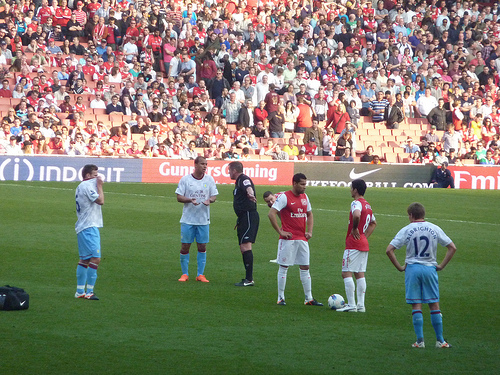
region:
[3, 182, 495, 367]
field where players are located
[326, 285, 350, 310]
ball on the field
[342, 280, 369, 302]
socks on the player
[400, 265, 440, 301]
shorts on the player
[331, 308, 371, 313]
shoes on the player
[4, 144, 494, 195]
banner on the wall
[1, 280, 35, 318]
bag on the ground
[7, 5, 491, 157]
crowd watching the game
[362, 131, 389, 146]
empty seats without people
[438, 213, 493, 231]
white line on field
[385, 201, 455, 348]
a soccer player wearing a white shirt and blue shorts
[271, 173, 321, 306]
a soccer player wearing a red jersey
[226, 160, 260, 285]
the referee wearing a black shirt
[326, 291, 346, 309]
a white soccer ball on the grass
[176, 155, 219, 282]
a man is wearing orange shoes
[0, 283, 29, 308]
a black bag in the grass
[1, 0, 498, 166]
spectators watching the game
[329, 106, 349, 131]
a person standing wearing a red shirt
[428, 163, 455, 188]
a man wearing black sitting on the grass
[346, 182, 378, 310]
a soccer player wearing white socks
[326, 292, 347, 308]
a white soccer ball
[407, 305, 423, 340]
a long blue sock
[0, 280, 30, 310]
a black and white bag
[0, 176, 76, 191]
a long white line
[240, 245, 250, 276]
a long black sock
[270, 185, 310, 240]
a man's red and white shirt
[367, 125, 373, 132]
a stadium seat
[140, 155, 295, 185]
a long red and white sign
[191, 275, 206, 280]
a man's orange shoe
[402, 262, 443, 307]
a man's blue shorts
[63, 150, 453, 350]
soccer players on the field during a game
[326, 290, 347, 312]
the soccer ball next to a player's feet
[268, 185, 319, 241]
one of the teams wears red jerseys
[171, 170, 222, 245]
one of the teams wears blue shorts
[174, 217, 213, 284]
the blue team's shorts match their hose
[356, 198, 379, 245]
this player is number 8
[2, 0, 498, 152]
the spectators watching the soccer game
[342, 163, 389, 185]
Nike is one of the sponsors of today's game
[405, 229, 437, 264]
this player is number 12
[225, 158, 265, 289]
the referee wears black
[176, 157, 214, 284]
soccer player on field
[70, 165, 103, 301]
soccer player on field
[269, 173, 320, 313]
soccer player on field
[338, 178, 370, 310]
soccer player on field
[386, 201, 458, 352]
soccer player on field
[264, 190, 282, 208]
soccer player on field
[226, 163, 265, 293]
soccer offical on field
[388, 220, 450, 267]
players white soccer jersey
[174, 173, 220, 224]
players white soccer jersey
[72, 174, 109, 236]
players white soccer jersey